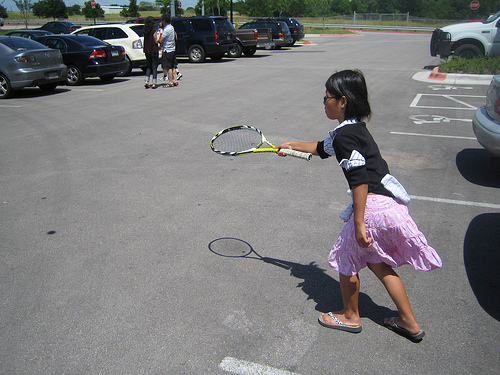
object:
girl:
[272, 67, 446, 342]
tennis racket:
[208, 122, 315, 163]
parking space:
[385, 107, 484, 138]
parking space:
[416, 84, 490, 96]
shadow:
[208, 236, 292, 271]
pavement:
[1, 30, 499, 374]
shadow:
[42, 228, 59, 237]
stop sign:
[91, 0, 97, 9]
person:
[142, 16, 162, 90]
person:
[157, 14, 179, 89]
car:
[1, 33, 69, 98]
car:
[30, 33, 131, 86]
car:
[68, 22, 167, 77]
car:
[134, 14, 238, 64]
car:
[221, 19, 274, 58]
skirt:
[327, 189, 444, 276]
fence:
[285, 10, 411, 24]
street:
[304, 23, 445, 37]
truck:
[430, 7, 500, 70]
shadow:
[261, 255, 402, 330]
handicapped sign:
[407, 113, 474, 125]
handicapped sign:
[427, 84, 474, 91]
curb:
[428, 64, 445, 82]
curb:
[303, 31, 361, 38]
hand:
[272, 141, 294, 158]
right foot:
[383, 314, 421, 336]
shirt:
[315, 116, 413, 222]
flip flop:
[382, 314, 427, 342]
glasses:
[323, 94, 336, 102]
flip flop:
[314, 311, 368, 334]